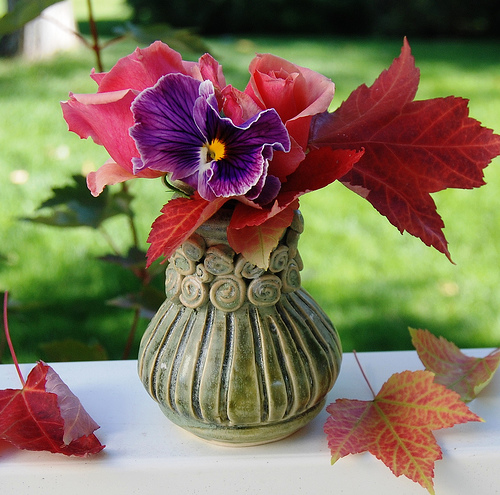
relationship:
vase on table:
[131, 202, 352, 448] [79, 327, 465, 491]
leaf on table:
[406, 324, 498, 414] [4, 346, 498, 492]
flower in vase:
[160, 91, 252, 178] [99, 202, 364, 452]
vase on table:
[131, 202, 352, 448] [4, 346, 498, 492]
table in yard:
[4, 358, 490, 493] [5, 61, 496, 353]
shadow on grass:
[360, 296, 467, 363] [48, 262, 154, 376]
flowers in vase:
[59, 35, 496, 271] [131, 202, 352, 448]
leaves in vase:
[258, 60, 468, 221] [131, 202, 352, 448]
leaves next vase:
[359, 297, 484, 459] [131, 202, 352, 448]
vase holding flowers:
[131, 202, 352, 448] [54, 32, 359, 230]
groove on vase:
[247, 312, 312, 419] [137, 211, 342, 446]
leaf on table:
[1, 336, 95, 468] [23, 345, 386, 490]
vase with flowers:
[131, 202, 352, 448] [51, 23, 485, 263]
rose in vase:
[223, 52, 335, 176] [137, 211, 342, 446]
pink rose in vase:
[226, 52, 332, 121] [131, 202, 352, 448]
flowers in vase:
[59, 35, 496, 271] [137, 211, 342, 446]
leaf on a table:
[1, 336, 95, 468] [23, 350, 426, 490]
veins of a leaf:
[331, 365, 460, 483] [328, 339, 485, 494]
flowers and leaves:
[59, 35, 496, 271] [139, 183, 201, 268]